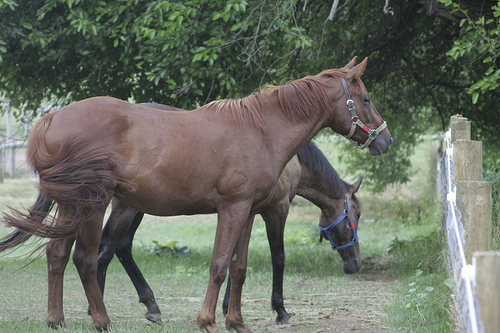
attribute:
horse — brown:
[80, 133, 361, 325]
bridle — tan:
[333, 77, 390, 147]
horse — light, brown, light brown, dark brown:
[27, 55, 393, 331]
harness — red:
[342, 115, 391, 145]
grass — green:
[387, 228, 469, 330]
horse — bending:
[284, 149, 388, 303]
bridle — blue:
[317, 178, 357, 251]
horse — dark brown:
[78, 119, 375, 324]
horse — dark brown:
[46, 25, 406, 331]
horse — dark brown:
[289, 147, 371, 317]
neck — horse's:
[211, 71, 340, 165]